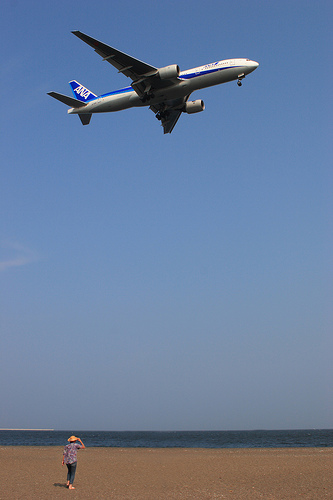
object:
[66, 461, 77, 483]
jeans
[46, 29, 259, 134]
aircraft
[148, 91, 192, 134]
wing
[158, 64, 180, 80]
engine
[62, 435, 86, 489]
person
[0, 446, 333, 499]
beach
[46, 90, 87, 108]
tail wing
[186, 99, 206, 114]
engine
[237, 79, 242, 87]
landing gear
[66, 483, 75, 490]
feet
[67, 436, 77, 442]
hat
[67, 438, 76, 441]
brim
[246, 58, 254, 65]
cockpit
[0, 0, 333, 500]
picture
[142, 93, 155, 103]
gear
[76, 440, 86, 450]
arm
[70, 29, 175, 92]
wing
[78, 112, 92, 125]
tail wing